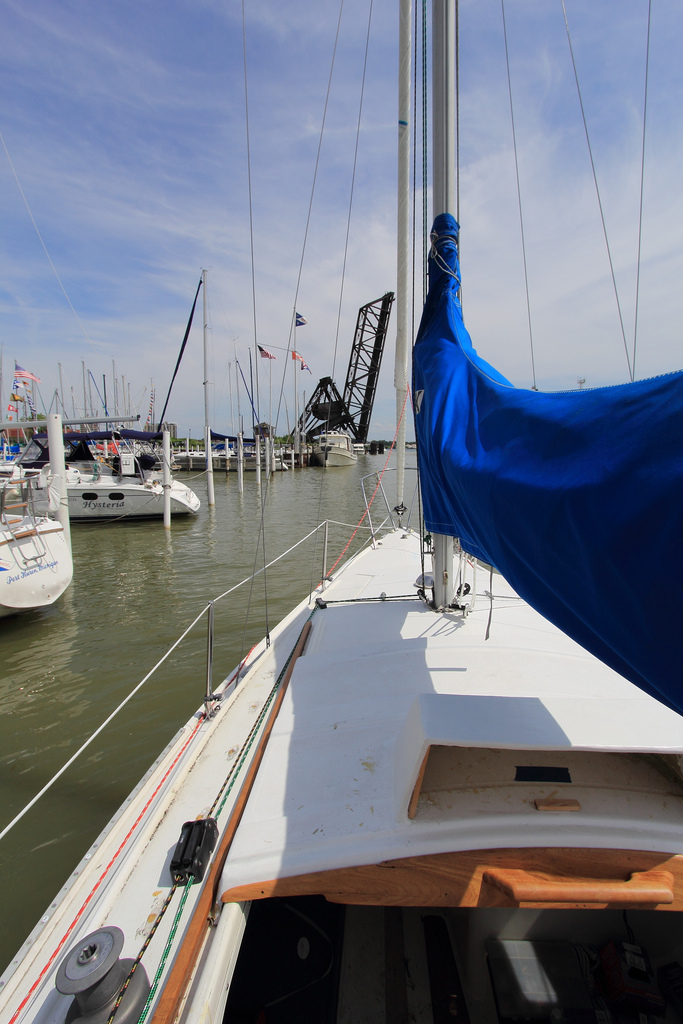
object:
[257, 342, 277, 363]
flag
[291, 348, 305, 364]
flag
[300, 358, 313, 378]
flag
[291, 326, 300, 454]
mast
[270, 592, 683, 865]
shadow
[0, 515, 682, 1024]
deck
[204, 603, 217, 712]
pole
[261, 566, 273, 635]
pole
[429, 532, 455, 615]
pole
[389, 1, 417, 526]
pole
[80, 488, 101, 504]
window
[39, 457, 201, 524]
boat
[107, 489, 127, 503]
window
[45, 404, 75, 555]
pole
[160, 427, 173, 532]
pole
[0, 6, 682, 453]
clouds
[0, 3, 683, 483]
sky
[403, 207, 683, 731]
canvas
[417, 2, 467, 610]
pole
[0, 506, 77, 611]
stern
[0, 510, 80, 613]
boat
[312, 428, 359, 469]
boat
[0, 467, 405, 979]
water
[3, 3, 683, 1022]
boat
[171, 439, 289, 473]
boat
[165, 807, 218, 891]
contraption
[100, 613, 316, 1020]
rope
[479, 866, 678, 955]
handle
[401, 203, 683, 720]
fabric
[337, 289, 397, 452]
bridge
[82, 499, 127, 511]
words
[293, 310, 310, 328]
flag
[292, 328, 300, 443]
rope